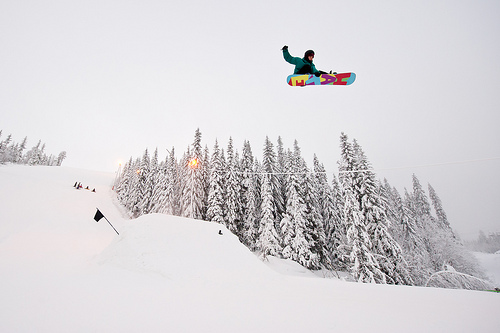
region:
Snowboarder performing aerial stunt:
[278, 40, 356, 90]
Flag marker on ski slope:
[88, 207, 117, 238]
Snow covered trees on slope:
[113, 127, 492, 289]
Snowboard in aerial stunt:
[287, 72, 357, 89]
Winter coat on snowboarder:
[283, 49, 320, 72]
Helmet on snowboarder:
[304, 49, 314, 57]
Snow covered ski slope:
[6, 164, 499, 331]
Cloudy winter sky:
[3, 2, 495, 234]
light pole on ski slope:
[186, 157, 201, 218]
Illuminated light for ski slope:
[188, 155, 200, 170]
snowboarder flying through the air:
[276, 41, 361, 89]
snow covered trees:
[120, 136, 487, 288]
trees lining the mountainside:
[114, 141, 489, 296]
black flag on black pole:
[94, 206, 118, 233]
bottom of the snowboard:
[286, 73, 355, 87]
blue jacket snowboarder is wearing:
[284, 53, 317, 69]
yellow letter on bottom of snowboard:
[292, 73, 306, 86]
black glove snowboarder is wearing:
[280, 46, 294, 51]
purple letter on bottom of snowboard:
[321, 75, 335, 87]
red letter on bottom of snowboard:
[333, 73, 349, 87]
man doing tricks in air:
[257, 35, 359, 96]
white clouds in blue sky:
[14, 29, 61, 59]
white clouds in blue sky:
[65, 32, 103, 52]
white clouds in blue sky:
[145, 29, 192, 54]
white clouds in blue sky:
[450, 35, 474, 62]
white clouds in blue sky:
[407, 49, 449, 100]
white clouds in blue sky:
[415, 116, 463, 146]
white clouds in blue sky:
[152, 48, 213, 90]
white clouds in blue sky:
[120, 42, 165, 94]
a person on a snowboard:
[280, 43, 356, 86]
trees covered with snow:
[111, 122, 496, 288]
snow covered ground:
[1, 160, 498, 331]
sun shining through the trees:
[183, 155, 198, 169]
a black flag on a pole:
[91, 205, 118, 233]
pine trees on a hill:
[111, 125, 499, 292]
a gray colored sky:
[0, 0, 499, 240]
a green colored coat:
[277, 45, 357, 75]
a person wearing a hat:
[280, 42, 338, 73]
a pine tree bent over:
[424, 268, 498, 292]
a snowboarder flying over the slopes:
[44, 10, 464, 299]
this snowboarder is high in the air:
[261, 35, 367, 92]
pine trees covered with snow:
[115, 118, 440, 285]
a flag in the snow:
[71, 209, 149, 254]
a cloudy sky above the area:
[25, 16, 226, 119]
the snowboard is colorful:
[271, 60, 376, 95]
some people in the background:
[64, 171, 111, 198]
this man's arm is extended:
[268, 36, 328, 70]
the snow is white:
[52, 229, 312, 307]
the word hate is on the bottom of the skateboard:
[285, 70, 355, 93]